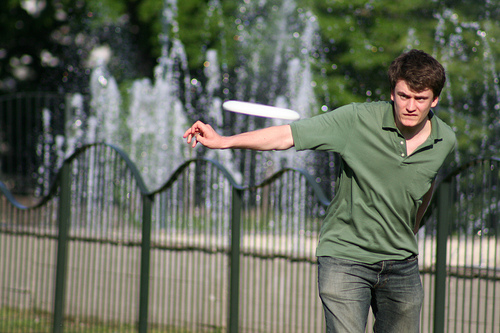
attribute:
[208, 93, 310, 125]
frisbee — white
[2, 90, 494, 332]
fence — green, metal, gree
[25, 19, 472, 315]
fountain — white